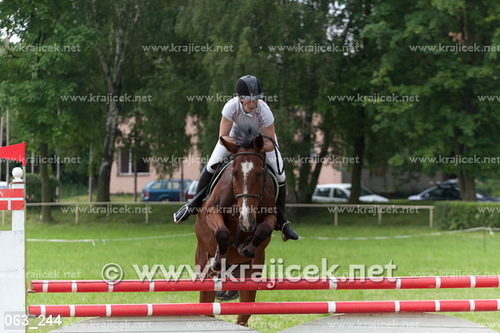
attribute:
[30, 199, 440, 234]
background fence — wooden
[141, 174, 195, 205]
car — blue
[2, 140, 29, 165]
flag —   red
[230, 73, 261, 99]
helmet — black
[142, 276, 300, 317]
poles — red, white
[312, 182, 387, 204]
vehicle — white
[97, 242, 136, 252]
grass — green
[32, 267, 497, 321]
gate — red, white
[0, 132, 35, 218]
flag — red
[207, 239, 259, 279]
hooves — up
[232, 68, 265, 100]
helmet — black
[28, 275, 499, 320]
jumping rails —  red and white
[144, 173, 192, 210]
car — blue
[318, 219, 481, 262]
grass — short, green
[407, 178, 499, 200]
car — parked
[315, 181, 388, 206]
car — parked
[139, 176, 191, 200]
car — parked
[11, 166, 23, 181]
knob — round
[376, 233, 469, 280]
grass — short, green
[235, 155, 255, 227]
fur — white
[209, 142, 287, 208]
pants — white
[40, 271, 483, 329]
marks — white